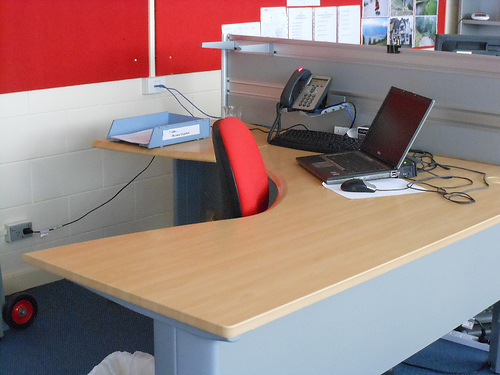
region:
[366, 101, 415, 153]
a laptop screen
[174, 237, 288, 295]
the desk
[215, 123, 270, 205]
a black and red chair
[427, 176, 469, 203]
a black cord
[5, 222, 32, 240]
a wall outlet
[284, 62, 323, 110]
a telephone that is black and grey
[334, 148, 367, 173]
the keyboard on the laptop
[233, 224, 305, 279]
the desk is brown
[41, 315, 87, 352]
the carpet is blue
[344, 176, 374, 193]
a mouse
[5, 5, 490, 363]
a minimal office desk scene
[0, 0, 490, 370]
a clean desk in a cubicle in an office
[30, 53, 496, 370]
a desk with a laptop computer on it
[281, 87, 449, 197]
a grey laptop computer with a mouse connected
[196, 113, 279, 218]
a red and black desk chair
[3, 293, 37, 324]
a red and black wheel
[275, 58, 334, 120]
a silver and grey phone with a red light on it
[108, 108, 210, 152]
a silver paper holder with white paper in it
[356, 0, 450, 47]
colorful pictures hung on the wall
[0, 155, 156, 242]
a grey outlet with a black cord plugged in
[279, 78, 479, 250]
a laptop on a table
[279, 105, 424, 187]
laptop on a desk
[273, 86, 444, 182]
an open laptop on a desk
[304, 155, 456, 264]
a mouse on a desk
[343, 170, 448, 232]
a computer mouse on a desk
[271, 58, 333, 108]
a phone on a stand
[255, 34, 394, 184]
a phone on the wal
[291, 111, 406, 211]
a keybaord on the desk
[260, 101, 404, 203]
a computer keyboard on the desk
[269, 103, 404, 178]
a black keyboard on the desk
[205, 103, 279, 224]
red chair pushed into a desk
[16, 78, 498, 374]
white desk with wooden top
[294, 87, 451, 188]
open laptop on desk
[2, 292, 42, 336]
red wheel on lower right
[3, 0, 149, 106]
empty red bulletin board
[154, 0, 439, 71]
red bulletin board with papers and photos attached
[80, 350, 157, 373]
trash can with white bag inside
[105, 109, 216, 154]
blue inbox with paper in it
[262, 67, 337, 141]
phone with red light on it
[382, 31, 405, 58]
black paper clamp attached to divider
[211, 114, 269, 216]
top of red office chair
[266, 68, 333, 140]
black and gray landline telephone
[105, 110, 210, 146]
blue tray on the desk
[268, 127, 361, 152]
black computer keyboard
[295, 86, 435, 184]
open laptop computer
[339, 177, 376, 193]
black and grey mouse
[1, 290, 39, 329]
black tire with red on the inside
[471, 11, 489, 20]
white clock on the shelf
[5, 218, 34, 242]
silver outlet on the wall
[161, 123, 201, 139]
white sticker on the side of the shelf